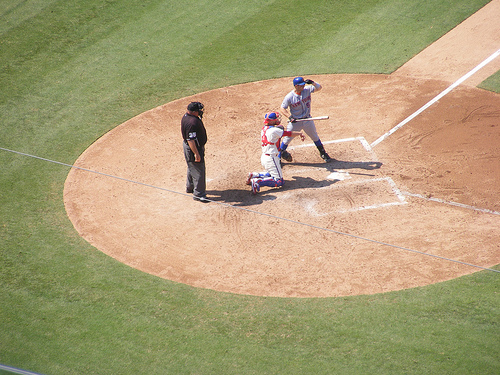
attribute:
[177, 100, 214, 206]
umpire — dressed, black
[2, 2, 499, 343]
game — baseball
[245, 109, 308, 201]
catcher — kneeling, baseball catcher, throwing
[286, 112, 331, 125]
bat — baseball bat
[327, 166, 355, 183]
plate — home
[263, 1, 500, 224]
diamond — baseball diamond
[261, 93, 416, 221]
box — batter's box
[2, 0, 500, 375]
grass — mowed, neat, patch, green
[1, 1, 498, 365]
field — baseball field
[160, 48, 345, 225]
players — three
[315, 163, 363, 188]
base — home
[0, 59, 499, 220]
markings — white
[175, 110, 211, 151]
shirt — black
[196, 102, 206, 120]
mask — black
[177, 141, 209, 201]
pants — grey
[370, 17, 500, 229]
lines — white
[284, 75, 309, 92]
helmet — blue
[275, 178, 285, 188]
pads — knee pads, blue